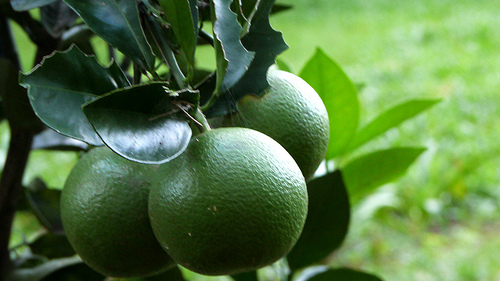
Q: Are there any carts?
A: No, there are no carts.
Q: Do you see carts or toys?
A: No, there are no carts or toys.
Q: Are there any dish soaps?
A: No, there are no dish soaps.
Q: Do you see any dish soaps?
A: No, there are no dish soaps.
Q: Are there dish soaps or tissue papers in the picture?
A: No, there are no dish soaps or tissue papers.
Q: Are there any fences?
A: No, there are no fences.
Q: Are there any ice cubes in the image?
A: No, there are no ice cubes.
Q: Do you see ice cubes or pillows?
A: No, there are no ice cubes or pillows.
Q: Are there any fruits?
A: Yes, there is a fruit.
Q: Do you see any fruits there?
A: Yes, there is a fruit.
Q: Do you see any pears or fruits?
A: Yes, there is a fruit.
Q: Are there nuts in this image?
A: No, there are no nuts.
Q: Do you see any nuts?
A: No, there are no nuts.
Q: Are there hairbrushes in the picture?
A: No, there are no hairbrushes.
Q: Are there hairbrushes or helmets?
A: No, there are no hairbrushes or helmets.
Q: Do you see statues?
A: No, there are no statues.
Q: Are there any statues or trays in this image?
A: No, there are no statues or trays.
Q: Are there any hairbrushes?
A: No, there are no hairbrushes.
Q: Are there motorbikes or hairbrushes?
A: No, there are no hairbrushes or motorbikes.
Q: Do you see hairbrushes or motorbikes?
A: No, there are no hairbrushes or motorbikes.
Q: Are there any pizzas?
A: Yes, there is a pizza.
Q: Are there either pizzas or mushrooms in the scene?
A: Yes, there is a pizza.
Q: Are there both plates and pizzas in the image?
A: Yes, there are both a pizza and a plate.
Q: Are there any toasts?
A: No, there are no toasts.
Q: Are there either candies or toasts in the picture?
A: No, there are no toasts or candies.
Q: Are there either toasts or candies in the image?
A: No, there are no toasts or candies.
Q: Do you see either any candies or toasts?
A: No, there are no toasts or candies.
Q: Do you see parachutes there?
A: No, there are no parachutes.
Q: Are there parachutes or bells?
A: No, there are no parachutes or bells.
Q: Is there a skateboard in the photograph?
A: No, there are no skateboards.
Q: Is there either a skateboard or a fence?
A: No, there are no skateboards or fences.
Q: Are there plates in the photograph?
A: Yes, there is a plate.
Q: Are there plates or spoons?
A: Yes, there is a plate.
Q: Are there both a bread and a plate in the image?
A: No, there is a plate but no breads.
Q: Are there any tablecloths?
A: No, there are no tablecloths.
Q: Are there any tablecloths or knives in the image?
A: No, there are no tablecloths or knives.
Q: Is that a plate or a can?
A: That is a plate.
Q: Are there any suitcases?
A: No, there are no suitcases.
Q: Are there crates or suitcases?
A: No, there are no suitcases or crates.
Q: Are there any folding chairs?
A: No, there are no folding chairs.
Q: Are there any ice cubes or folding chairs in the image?
A: No, there are no folding chairs or ice cubes.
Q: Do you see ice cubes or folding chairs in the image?
A: No, there are no folding chairs or ice cubes.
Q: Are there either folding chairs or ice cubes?
A: No, there are no folding chairs or ice cubes.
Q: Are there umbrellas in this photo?
A: No, there are no umbrellas.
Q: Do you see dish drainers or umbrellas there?
A: No, there are no umbrellas or dish drainers.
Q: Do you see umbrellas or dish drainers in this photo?
A: No, there are no umbrellas or dish drainers.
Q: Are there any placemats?
A: No, there are no placemats.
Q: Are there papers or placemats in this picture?
A: No, there are no placemats or papers.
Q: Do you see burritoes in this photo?
A: No, there are no burritoes.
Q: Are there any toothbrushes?
A: No, there are no toothbrushes.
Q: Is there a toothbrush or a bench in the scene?
A: No, there are no toothbrushes or benches.